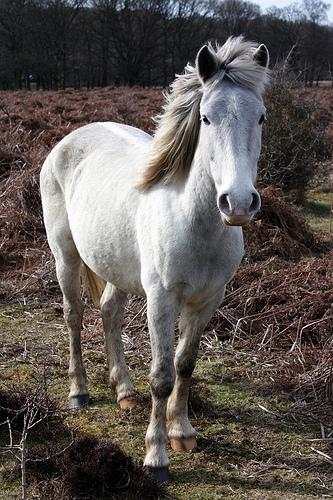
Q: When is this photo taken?
A: Daytime.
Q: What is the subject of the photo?
A: Horse.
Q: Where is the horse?
A: Field.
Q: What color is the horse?
A: White.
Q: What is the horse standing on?
A: Grass.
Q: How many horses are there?
A: One.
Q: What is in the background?
A: Trees.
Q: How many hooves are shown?
A: Four.